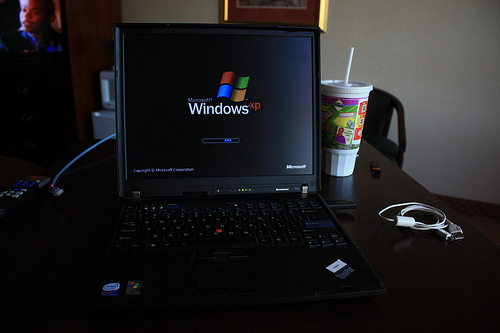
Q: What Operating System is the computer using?
A: Windows XP.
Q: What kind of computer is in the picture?
A: Laptop.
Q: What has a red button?
A: A keyboard.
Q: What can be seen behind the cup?
A: Part of a chair.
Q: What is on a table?
A: An open laptop.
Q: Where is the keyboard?
A: On a laptop.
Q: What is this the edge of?
A: A laptop.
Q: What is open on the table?
A: A laptop.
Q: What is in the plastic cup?
A: A straw.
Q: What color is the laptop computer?
A: Black.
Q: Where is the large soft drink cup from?
A: A fast food restaurant or store.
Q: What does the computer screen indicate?
A: Windows XP.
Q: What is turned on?
A: Computer screen.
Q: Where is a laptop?
A: On a table.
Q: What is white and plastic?
A: Tall cup.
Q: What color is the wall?
A: White.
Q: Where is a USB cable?
A: On the table.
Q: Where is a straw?
A: In drink container.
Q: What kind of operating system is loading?
A: Microsoft XP.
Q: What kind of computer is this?
A: ThinkPad.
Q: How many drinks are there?
A: 1.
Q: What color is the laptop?
A: Black.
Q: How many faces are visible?
A: 1.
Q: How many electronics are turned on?
A: 2.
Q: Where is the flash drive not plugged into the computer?
A: Beside the drink.